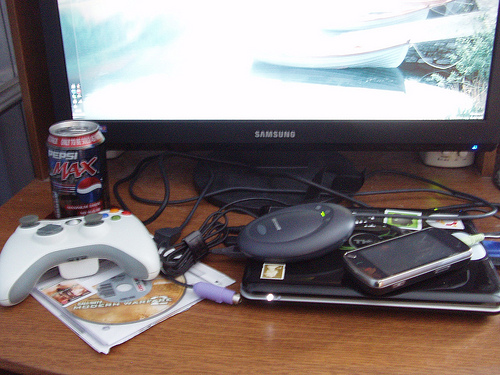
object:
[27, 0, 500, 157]
computer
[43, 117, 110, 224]
pepsi max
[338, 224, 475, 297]
cellphone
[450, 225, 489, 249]
plug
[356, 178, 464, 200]
wires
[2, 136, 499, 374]
table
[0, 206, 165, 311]
electronics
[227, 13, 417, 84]
boat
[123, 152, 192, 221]
cord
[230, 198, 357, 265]
mouse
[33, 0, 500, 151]
monitor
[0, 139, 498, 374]
desk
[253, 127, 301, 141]
samsung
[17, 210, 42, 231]
buttons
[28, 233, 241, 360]
case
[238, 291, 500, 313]
edge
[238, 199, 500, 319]
laptop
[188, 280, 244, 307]
purple cap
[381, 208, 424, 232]
stickers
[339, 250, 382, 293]
edge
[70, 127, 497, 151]
edge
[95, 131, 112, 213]
side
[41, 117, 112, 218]
soda can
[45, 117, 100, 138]
top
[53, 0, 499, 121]
screen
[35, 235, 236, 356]
disks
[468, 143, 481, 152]
light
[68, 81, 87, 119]
icons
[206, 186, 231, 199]
cables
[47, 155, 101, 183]
max